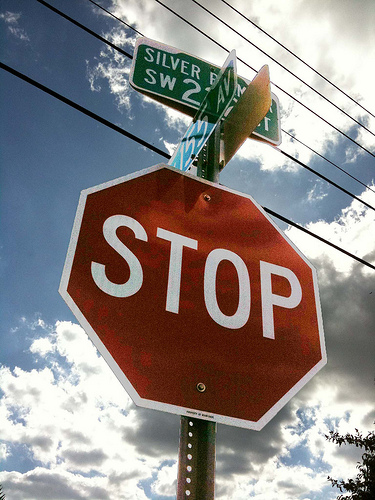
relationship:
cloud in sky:
[0, 0, 375, 499] [0, 1, 375, 498]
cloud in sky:
[0, 176, 375, 498] [0, 1, 375, 498]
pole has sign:
[176, 107, 242, 499] [127, 37, 285, 142]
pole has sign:
[176, 107, 242, 499] [66, 163, 328, 426]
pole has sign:
[176, 107, 242, 499] [151, 55, 283, 176]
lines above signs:
[0, 0, 375, 274] [67, 32, 335, 432]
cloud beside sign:
[0, 0, 375, 499] [57, 25, 336, 444]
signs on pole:
[67, 32, 335, 432] [176, 410, 221, 498]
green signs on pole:
[129, 37, 282, 145] [184, 106, 233, 177]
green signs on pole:
[129, 37, 282, 145] [175, 419, 215, 498]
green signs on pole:
[131, 37, 284, 169] [171, 415, 218, 496]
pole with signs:
[176, 107, 222, 499] [123, 31, 291, 181]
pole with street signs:
[176, 107, 222, 499] [103, 23, 319, 162]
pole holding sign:
[176, 107, 222, 499] [50, 161, 332, 437]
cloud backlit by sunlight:
[0, 0, 375, 499] [24, 334, 91, 453]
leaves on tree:
[362, 455, 371, 468] [349, 468, 363, 499]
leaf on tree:
[328, 425, 339, 443] [349, 468, 363, 499]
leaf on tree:
[331, 472, 344, 489] [349, 468, 363, 499]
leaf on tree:
[345, 424, 360, 447] [349, 468, 363, 499]